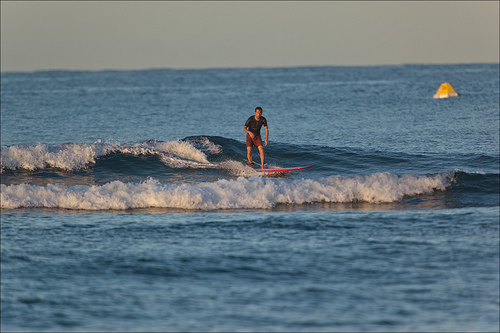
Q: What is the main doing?
A: Surfing.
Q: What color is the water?
A: Blue.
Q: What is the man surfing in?
A: Water.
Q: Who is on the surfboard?
A: A man.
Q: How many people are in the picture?
A: One.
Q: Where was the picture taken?
A: At the ocean.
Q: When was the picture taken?
A: During the day.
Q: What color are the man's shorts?
A: Red.